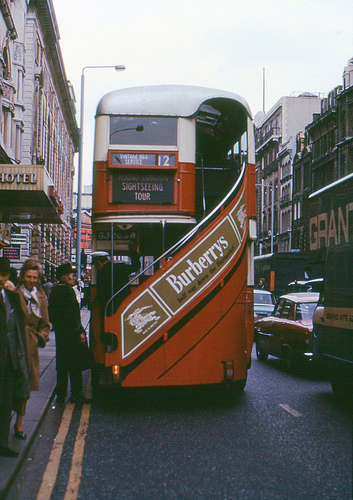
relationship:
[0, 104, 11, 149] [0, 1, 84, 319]
window on building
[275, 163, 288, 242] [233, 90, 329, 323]
window on building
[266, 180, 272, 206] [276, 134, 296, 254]
window on building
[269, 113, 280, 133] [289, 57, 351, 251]
window adorning building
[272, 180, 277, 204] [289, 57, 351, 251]
window adorning building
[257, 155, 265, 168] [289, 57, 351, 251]
window adorning building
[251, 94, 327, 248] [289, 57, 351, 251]
building adorning building